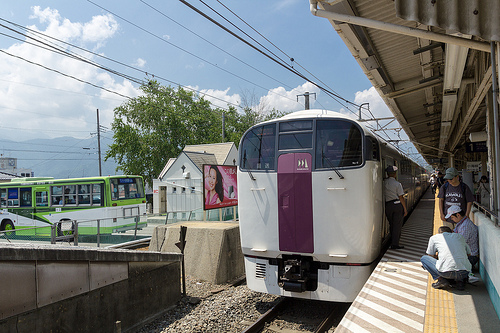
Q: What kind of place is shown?
A: It is a station.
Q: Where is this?
A: This is at the station.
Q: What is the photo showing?
A: It is showing a station.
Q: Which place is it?
A: It is a station.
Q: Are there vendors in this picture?
A: No, there are no vendors.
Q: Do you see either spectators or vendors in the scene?
A: No, there are no vendors or spectators.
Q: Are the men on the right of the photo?
A: Yes, the men are on the right of the image.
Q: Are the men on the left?
A: No, the men are on the right of the image.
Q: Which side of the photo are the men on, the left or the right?
A: The men are on the right of the image.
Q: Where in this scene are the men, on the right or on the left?
A: The men are on the right of the image.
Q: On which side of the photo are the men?
A: The men are on the right of the image.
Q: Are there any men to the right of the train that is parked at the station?
A: Yes, there are men to the right of the train.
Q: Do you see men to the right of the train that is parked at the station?
A: Yes, there are men to the right of the train.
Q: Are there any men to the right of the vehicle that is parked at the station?
A: Yes, there are men to the right of the train.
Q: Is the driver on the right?
A: Yes, the driver is on the right of the image.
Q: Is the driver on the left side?
A: No, the driver is on the right of the image.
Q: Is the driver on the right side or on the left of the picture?
A: The driver is on the right of the image.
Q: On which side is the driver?
A: The driver is on the right of the image.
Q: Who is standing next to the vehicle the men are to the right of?
A: The driver is standing next to the train.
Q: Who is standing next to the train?
A: The driver is standing next to the train.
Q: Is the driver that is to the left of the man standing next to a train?
A: Yes, the driver is standing next to a train.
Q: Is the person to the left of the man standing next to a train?
A: Yes, the driver is standing next to a train.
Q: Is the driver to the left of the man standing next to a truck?
A: No, the driver is standing next to a train.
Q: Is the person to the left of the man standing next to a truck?
A: No, the driver is standing next to a train.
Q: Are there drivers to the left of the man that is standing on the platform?
A: Yes, there is a driver to the left of the man.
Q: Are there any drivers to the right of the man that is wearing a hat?
A: No, the driver is to the left of the man.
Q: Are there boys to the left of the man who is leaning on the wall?
A: No, there is a driver to the left of the man.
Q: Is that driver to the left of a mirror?
A: No, the driver is to the left of a man.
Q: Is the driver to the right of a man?
A: No, the driver is to the left of a man.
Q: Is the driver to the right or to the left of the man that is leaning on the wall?
A: The driver is to the left of the man.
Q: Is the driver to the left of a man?
A: Yes, the driver is to the left of a man.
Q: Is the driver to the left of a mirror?
A: No, the driver is to the left of a man.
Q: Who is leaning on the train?
A: The driver is leaning on the train.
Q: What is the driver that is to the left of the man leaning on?
A: The driver is leaning on the train.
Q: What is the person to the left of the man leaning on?
A: The driver is leaning on the train.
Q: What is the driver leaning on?
A: The driver is leaning on the train.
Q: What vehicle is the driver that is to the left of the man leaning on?
A: The driver is leaning on the train.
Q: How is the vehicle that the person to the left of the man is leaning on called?
A: The vehicle is a train.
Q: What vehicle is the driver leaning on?
A: The driver is leaning on the train.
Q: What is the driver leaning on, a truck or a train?
A: The driver is leaning on a train.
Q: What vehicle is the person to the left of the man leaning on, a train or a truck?
A: The driver is leaning on a train.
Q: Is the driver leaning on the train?
A: Yes, the driver is leaning on the train.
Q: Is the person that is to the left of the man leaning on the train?
A: Yes, the driver is leaning on the train.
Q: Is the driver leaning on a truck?
A: No, the driver is leaning on the train.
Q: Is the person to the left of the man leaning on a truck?
A: No, the driver is leaning on the train.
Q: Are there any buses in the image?
A: Yes, there is a bus.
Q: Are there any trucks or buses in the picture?
A: Yes, there is a bus.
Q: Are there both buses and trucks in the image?
A: No, there is a bus but no trucks.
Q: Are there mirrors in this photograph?
A: No, there are no mirrors.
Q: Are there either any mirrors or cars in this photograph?
A: No, there are no mirrors or cars.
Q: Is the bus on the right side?
A: No, the bus is on the left of the image.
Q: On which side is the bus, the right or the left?
A: The bus is on the left of the image.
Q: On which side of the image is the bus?
A: The bus is on the left of the image.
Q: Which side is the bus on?
A: The bus is on the left of the image.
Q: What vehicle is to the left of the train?
A: The vehicle is a bus.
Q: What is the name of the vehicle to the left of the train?
A: The vehicle is a bus.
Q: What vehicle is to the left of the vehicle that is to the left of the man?
A: The vehicle is a bus.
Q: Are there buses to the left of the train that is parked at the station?
A: Yes, there is a bus to the left of the train.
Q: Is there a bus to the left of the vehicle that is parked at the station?
A: Yes, there is a bus to the left of the train.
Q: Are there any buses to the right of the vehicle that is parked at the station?
A: No, the bus is to the left of the train.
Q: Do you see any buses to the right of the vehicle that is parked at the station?
A: No, the bus is to the left of the train.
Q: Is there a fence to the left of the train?
A: No, there is a bus to the left of the train.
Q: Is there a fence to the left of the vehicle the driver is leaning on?
A: No, there is a bus to the left of the train.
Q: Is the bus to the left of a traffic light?
A: No, the bus is to the left of the train.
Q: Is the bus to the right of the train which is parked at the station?
A: No, the bus is to the left of the train.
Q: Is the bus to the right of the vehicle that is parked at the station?
A: No, the bus is to the left of the train.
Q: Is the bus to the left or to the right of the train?
A: The bus is to the left of the train.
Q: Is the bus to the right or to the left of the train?
A: The bus is to the left of the train.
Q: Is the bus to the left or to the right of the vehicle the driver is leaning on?
A: The bus is to the left of the train.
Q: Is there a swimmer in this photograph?
A: No, there are no swimmers.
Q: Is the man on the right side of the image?
A: Yes, the man is on the right of the image.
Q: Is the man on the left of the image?
A: No, the man is on the right of the image.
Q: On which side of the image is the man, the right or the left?
A: The man is on the right of the image.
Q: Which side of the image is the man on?
A: The man is on the right of the image.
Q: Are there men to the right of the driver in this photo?
A: Yes, there is a man to the right of the driver.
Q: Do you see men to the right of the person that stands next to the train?
A: Yes, there is a man to the right of the driver.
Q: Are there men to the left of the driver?
A: No, the man is to the right of the driver.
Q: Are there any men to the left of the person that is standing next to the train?
A: No, the man is to the right of the driver.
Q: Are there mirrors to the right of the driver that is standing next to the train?
A: No, there is a man to the right of the driver.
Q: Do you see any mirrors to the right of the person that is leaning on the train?
A: No, there is a man to the right of the driver.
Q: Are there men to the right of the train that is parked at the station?
A: Yes, there is a man to the right of the train.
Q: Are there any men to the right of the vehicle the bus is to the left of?
A: Yes, there is a man to the right of the train.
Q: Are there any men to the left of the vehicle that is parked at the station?
A: No, the man is to the right of the train.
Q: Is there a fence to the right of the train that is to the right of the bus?
A: No, there is a man to the right of the train.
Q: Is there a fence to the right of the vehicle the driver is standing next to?
A: No, there is a man to the right of the train.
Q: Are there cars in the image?
A: No, there are no cars.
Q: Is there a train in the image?
A: Yes, there is a train.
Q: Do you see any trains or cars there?
A: Yes, there is a train.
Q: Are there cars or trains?
A: Yes, there is a train.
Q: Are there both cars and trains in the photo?
A: No, there is a train but no cars.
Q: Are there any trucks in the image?
A: No, there are no trucks.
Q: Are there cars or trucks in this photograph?
A: No, there are no trucks or cars.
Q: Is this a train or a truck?
A: This is a train.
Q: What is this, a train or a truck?
A: This is a train.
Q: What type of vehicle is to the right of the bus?
A: The vehicle is a train.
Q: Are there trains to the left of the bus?
A: No, the train is to the right of the bus.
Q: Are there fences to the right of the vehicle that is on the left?
A: No, there is a train to the right of the bus.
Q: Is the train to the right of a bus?
A: Yes, the train is to the right of a bus.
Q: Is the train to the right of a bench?
A: No, the train is to the right of a bus.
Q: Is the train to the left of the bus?
A: No, the train is to the right of the bus.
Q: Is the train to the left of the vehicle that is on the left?
A: No, the train is to the right of the bus.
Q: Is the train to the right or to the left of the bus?
A: The train is to the right of the bus.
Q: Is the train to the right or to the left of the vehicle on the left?
A: The train is to the right of the bus.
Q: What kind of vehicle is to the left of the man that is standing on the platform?
A: The vehicle is a train.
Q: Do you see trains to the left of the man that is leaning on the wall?
A: Yes, there is a train to the left of the man.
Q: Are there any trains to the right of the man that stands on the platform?
A: No, the train is to the left of the man.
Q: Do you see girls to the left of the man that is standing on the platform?
A: No, there is a train to the left of the man.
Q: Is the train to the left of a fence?
A: No, the train is to the left of the man.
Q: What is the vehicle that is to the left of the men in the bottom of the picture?
A: The vehicle is a train.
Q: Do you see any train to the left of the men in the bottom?
A: Yes, there is a train to the left of the men.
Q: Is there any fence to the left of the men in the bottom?
A: No, there is a train to the left of the men.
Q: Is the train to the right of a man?
A: No, the train is to the left of a man.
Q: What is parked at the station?
A: The train is parked at the station.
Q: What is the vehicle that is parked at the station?
A: The vehicle is a train.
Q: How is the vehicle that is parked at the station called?
A: The vehicle is a train.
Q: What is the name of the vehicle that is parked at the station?
A: The vehicle is a train.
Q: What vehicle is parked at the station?
A: The vehicle is a train.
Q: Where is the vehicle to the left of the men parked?
A: The train is parked at the station.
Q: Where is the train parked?
A: The train is parked at the station.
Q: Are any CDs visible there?
A: No, there are no cds.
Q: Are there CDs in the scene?
A: No, there are no cds.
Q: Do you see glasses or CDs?
A: No, there are no CDs or glasses.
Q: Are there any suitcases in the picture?
A: No, there are no suitcases.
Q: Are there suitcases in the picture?
A: No, there are no suitcases.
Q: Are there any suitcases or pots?
A: No, there are no suitcases or pots.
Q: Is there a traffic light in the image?
A: No, there are no traffic lights.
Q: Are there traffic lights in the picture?
A: No, there are no traffic lights.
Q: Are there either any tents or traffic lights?
A: No, there are no traffic lights or tents.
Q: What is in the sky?
A: The clouds are in the sky.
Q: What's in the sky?
A: The clouds are in the sky.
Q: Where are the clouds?
A: The clouds are in the sky.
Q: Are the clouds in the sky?
A: Yes, the clouds are in the sky.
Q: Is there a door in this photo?
A: Yes, there is a door.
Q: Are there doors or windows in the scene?
A: Yes, there is a door.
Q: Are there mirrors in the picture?
A: No, there are no mirrors.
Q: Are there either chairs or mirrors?
A: No, there are no mirrors or chairs.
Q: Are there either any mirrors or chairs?
A: No, there are no mirrors or chairs.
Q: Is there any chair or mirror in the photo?
A: No, there are no mirrors or chairs.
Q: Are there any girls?
A: No, there are no girls.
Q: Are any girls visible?
A: No, there are no girls.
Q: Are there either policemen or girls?
A: No, there are no girls or policemen.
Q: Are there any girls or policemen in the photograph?
A: No, there are no girls or policemen.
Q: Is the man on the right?
A: Yes, the man is on the right of the image.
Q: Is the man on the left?
A: No, the man is on the right of the image.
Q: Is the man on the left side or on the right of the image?
A: The man is on the right of the image.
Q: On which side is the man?
A: The man is on the right of the image.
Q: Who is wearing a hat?
A: The man is wearing a hat.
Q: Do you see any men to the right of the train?
A: Yes, there is a man to the right of the train.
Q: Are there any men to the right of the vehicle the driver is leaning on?
A: Yes, there is a man to the right of the train.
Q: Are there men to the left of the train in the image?
A: No, the man is to the right of the train.